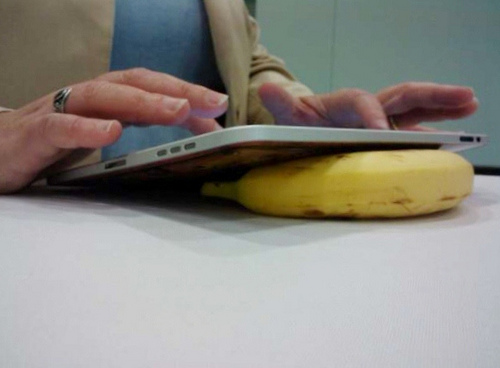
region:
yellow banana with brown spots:
[190, 141, 498, 226]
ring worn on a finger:
[33, 74, 92, 119]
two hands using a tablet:
[9, 26, 486, 231]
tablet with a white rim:
[114, 114, 491, 174]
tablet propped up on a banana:
[105, 111, 498, 251]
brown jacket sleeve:
[203, 0, 327, 127]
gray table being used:
[6, 197, 498, 358]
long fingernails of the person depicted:
[202, 87, 234, 117]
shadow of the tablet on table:
[137, 201, 306, 266]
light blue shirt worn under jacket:
[101, 0, 251, 162]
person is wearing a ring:
[37, 72, 123, 127]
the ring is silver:
[47, 78, 85, 108]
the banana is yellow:
[210, 145, 486, 240]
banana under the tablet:
[72, 116, 488, 237]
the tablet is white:
[74, 101, 496, 211]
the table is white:
[57, 239, 234, 359]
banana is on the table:
[140, 117, 486, 257]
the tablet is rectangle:
[48, 87, 498, 202]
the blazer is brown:
[0, 14, 273, 121]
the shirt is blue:
[127, 27, 222, 132]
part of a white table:
[246, 257, 390, 334]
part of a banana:
[345, 173, 402, 215]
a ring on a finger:
[42, 75, 71, 107]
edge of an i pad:
[163, 130, 228, 151]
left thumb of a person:
[262, 85, 300, 114]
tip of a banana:
[204, 183, 237, 208]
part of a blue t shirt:
[145, 31, 195, 68]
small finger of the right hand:
[43, 114, 113, 146]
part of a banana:
[347, 172, 405, 219]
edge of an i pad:
[216, 135, 252, 148]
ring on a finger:
[53, 75, 70, 110]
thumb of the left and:
[265, 84, 298, 124]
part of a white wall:
[320, 5, 447, 70]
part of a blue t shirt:
[121, 12, 187, 67]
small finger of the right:
[0, 121, 180, 141]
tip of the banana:
[196, 172, 243, 210]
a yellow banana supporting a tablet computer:
[204, 146, 478, 226]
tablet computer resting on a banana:
[59, 121, 493, 181]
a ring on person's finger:
[49, 81, 78, 119]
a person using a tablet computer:
[4, 5, 491, 178]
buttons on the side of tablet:
[94, 137, 208, 177]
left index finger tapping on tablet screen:
[330, 85, 397, 135]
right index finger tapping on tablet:
[177, 116, 230, 132]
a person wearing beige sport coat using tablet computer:
[0, 1, 495, 192]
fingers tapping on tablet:
[3, 71, 493, 186]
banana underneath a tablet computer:
[198, 144, 486, 218]